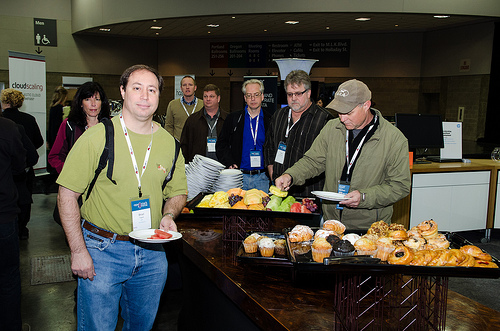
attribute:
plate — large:
[248, 234, 477, 279]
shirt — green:
[55, 114, 188, 236]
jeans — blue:
[76, 217, 170, 329]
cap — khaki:
[324, 80, 370, 113]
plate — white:
[310, 190, 351, 205]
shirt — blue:
[243, 104, 263, 173]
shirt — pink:
[47, 116, 88, 174]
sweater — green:
[163, 93, 206, 139]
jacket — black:
[220, 104, 272, 162]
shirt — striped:
[261, 106, 336, 195]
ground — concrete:
[7, 194, 74, 331]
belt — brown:
[78, 216, 134, 241]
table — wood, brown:
[171, 220, 496, 330]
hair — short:
[119, 65, 164, 90]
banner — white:
[7, 57, 51, 176]